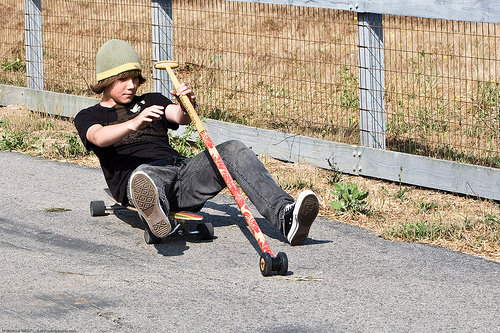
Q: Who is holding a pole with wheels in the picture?
A: The boy in the black shirt.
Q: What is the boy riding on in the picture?
A: Skateboard.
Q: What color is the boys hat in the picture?
A: Green and yellow.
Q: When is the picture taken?
A: Daytime.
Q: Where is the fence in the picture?
A: Behind the boy.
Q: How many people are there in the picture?
A: One.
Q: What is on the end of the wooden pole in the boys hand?
A: Wheels.